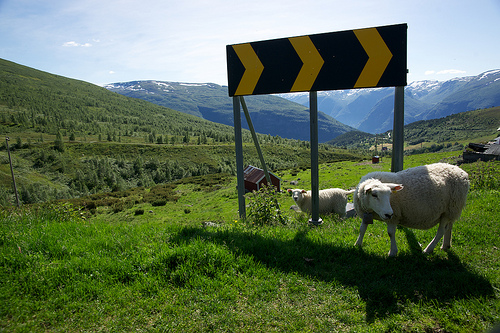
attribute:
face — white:
[371, 180, 406, 231]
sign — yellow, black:
[210, 17, 439, 127]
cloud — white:
[426, 62, 461, 84]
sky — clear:
[402, 9, 488, 128]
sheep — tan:
[338, 153, 479, 277]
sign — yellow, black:
[211, 16, 401, 116]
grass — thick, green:
[108, 208, 215, 292]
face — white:
[354, 166, 417, 245]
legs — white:
[390, 220, 456, 280]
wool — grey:
[393, 160, 470, 225]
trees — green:
[75, 158, 175, 193]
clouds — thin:
[55, 17, 185, 65]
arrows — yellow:
[287, 33, 326, 91]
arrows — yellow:
[350, 26, 391, 89]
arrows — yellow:
[232, 40, 262, 96]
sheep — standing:
[280, 159, 470, 251]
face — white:
[365, 181, 401, 224]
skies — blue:
[52, 8, 469, 66]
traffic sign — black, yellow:
[226, 24, 408, 223]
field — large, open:
[1, 56, 499, 330]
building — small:
[242, 164, 280, 193]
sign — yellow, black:
[227, 21, 409, 223]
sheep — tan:
[353, 160, 469, 260]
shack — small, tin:
[239, 160, 279, 192]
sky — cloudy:
[1, 0, 499, 87]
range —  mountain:
[118, 54, 452, 131]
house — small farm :
[363, 126, 414, 155]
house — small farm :
[354, 121, 419, 160]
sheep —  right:
[274, 165, 371, 237]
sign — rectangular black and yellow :
[211, 20, 413, 249]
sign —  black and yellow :
[224, 10, 412, 240]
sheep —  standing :
[344, 154, 467, 254]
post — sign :
[387, 91, 416, 248]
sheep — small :
[284, 182, 344, 218]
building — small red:
[359, 130, 436, 152]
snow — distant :
[146, 70, 170, 82]